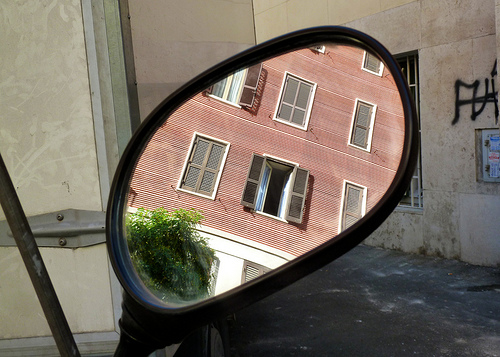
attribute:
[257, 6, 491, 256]
wall — Outer side 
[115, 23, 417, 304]
mirror — connected, reflecting, attached, side, black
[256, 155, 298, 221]
window — open, closed, skinny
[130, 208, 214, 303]
tree — green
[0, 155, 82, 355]
rod — steel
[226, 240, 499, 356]
ground — pavement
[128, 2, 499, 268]
structure — beige, white, dirty, blank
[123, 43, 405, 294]
building — brick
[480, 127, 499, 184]
sign — white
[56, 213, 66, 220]
screw — grey, small